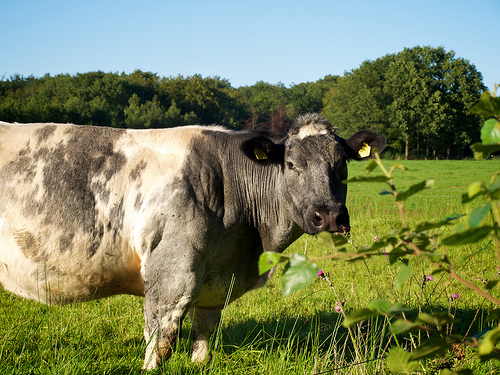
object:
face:
[284, 127, 344, 235]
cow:
[2, 110, 349, 374]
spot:
[130, 154, 153, 183]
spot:
[137, 189, 143, 212]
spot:
[103, 152, 129, 179]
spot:
[27, 233, 45, 255]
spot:
[33, 267, 68, 279]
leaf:
[346, 173, 394, 188]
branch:
[257, 138, 499, 312]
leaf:
[478, 118, 499, 148]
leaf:
[395, 176, 435, 203]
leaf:
[441, 218, 494, 253]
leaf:
[281, 260, 320, 295]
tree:
[382, 50, 477, 145]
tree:
[316, 60, 392, 143]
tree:
[275, 80, 337, 123]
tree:
[217, 85, 250, 126]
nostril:
[310, 212, 326, 226]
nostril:
[334, 210, 349, 229]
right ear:
[239, 137, 287, 170]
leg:
[140, 259, 196, 374]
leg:
[186, 294, 227, 367]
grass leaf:
[208, 271, 247, 367]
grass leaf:
[271, 308, 282, 367]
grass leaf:
[326, 296, 339, 369]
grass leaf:
[368, 302, 386, 374]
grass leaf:
[53, 281, 66, 373]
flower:
[316, 268, 325, 279]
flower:
[427, 274, 435, 280]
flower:
[449, 289, 456, 302]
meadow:
[0, 156, 497, 374]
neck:
[223, 132, 296, 255]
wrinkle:
[240, 142, 251, 229]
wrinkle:
[250, 162, 259, 229]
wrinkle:
[255, 168, 271, 249]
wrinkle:
[265, 166, 276, 232]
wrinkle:
[230, 137, 251, 224]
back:
[3, 122, 205, 248]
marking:
[44, 124, 109, 249]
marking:
[2, 148, 44, 223]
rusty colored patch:
[100, 250, 150, 296]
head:
[242, 116, 378, 235]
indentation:
[149, 232, 165, 251]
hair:
[290, 112, 331, 127]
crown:
[296, 122, 330, 140]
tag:
[254, 146, 268, 161]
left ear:
[340, 132, 388, 159]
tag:
[358, 142, 371, 161]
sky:
[3, 3, 497, 88]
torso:
[1, 122, 159, 306]